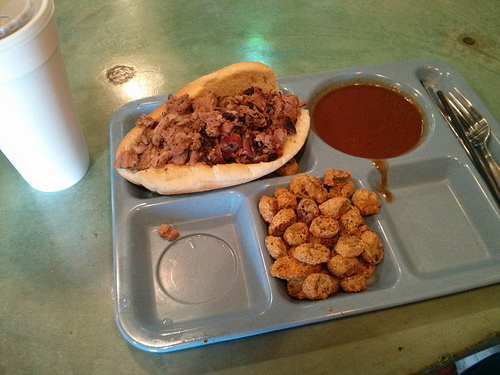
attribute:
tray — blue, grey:
[99, 55, 499, 349]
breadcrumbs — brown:
[256, 172, 386, 306]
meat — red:
[105, 92, 306, 168]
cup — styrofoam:
[0, 2, 92, 205]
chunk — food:
[180, 104, 259, 163]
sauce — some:
[304, 81, 430, 160]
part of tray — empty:
[136, 243, 258, 341]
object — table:
[69, 9, 181, 86]